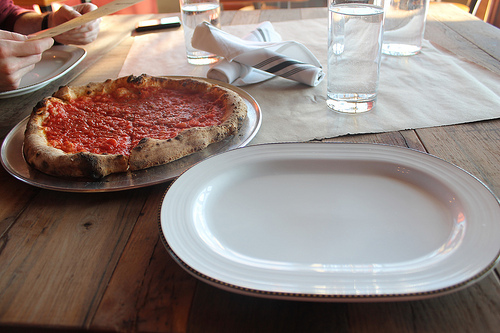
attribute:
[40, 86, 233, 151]
sauce — red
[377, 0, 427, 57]
glass — clear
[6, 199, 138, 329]
table — brown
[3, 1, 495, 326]
table — wooden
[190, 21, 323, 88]
napkin — roleld up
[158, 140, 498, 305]
serving plate — white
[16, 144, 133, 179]
pizza crust — cooked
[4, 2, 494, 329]
wood table — wooden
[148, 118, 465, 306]
plate — oval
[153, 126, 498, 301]
plate — white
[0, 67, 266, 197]
plate — metal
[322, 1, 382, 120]
glass water — clear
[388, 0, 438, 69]
glass water — clear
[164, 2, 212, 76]
glass water — clear